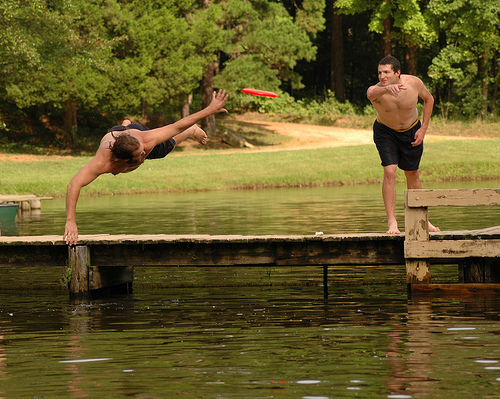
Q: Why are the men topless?
A: The men are swimming.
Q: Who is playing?
A: Two men.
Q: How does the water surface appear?
A: Smooth.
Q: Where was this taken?
A: At a lake.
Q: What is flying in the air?
A: A frisbee.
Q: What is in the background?
A: Trees.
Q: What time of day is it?
A: Day time.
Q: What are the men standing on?
A: A dock.